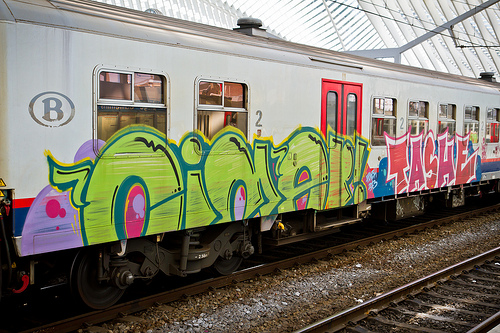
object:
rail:
[296, 243, 500, 331]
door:
[320, 79, 366, 211]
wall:
[272, 0, 398, 43]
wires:
[341, 2, 500, 78]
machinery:
[8, 259, 33, 314]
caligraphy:
[45, 124, 370, 245]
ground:
[413, 141, 463, 196]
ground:
[70, 191, 500, 333]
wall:
[258, 85, 295, 171]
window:
[196, 79, 251, 153]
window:
[90, 63, 164, 158]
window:
[369, 97, 399, 146]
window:
[406, 97, 428, 144]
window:
[435, 104, 460, 147]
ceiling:
[92, 0, 498, 79]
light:
[251, 0, 358, 51]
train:
[1, 0, 498, 324]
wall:
[132, 157, 218, 200]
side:
[0, 0, 499, 258]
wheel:
[69, 246, 128, 311]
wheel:
[214, 251, 243, 275]